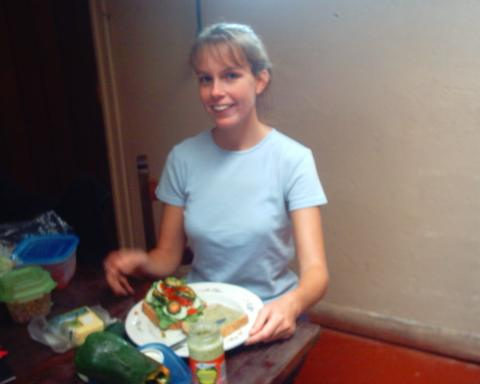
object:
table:
[0, 260, 480, 384]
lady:
[103, 23, 329, 346]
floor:
[286, 327, 480, 384]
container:
[9, 233, 80, 289]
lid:
[9, 232, 78, 268]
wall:
[328, 0, 480, 251]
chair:
[136, 153, 194, 266]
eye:
[226, 73, 242, 81]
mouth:
[212, 105, 233, 112]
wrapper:
[0, 208, 73, 243]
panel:
[0, 0, 121, 270]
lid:
[0, 264, 58, 303]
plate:
[125, 282, 264, 358]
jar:
[187, 322, 227, 384]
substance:
[187, 322, 229, 384]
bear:
[104, 23, 329, 346]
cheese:
[48, 306, 105, 347]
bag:
[27, 305, 117, 354]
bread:
[142, 300, 208, 330]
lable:
[194, 363, 219, 384]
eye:
[200, 75, 211, 83]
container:
[0, 264, 57, 326]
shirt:
[154, 127, 328, 322]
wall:
[138, 84, 189, 125]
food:
[141, 275, 248, 338]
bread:
[181, 304, 249, 337]